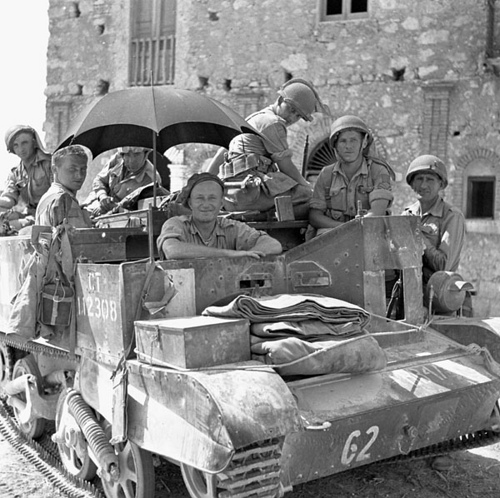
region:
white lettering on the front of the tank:
[331, 423, 381, 459]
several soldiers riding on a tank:
[4, 83, 473, 305]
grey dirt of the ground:
[409, 470, 471, 495]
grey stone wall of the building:
[350, 7, 425, 114]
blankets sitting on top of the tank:
[203, 282, 393, 386]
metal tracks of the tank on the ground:
[18, 431, 79, 496]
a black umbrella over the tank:
[58, 79, 258, 177]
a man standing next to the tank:
[401, 151, 478, 308]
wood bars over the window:
[124, 36, 179, 88]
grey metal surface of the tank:
[221, 374, 283, 425]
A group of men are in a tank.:
[0, 0, 496, 495]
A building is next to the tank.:
[45, 2, 498, 262]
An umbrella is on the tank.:
[51, 60, 256, 248]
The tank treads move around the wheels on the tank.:
[0, 327, 166, 494]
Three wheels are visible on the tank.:
[1, 356, 149, 496]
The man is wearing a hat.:
[175, 168, 225, 219]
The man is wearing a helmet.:
[405, 150, 451, 201]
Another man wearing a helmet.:
[271, 76, 316, 123]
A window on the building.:
[463, 170, 495, 220]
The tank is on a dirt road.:
[0, 292, 499, 497]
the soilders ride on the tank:
[1, 74, 493, 481]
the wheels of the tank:
[1, 352, 147, 495]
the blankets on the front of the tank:
[214, 288, 384, 372]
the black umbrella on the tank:
[77, 74, 269, 157]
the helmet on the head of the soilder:
[324, 111, 374, 155]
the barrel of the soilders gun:
[297, 132, 312, 178]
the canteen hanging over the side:
[42, 273, 77, 341]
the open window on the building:
[461, 173, 498, 218]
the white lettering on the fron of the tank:
[334, 422, 379, 469]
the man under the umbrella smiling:
[161, 166, 286, 259]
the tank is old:
[121, 310, 306, 492]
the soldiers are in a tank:
[5, 66, 470, 223]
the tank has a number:
[311, 418, 398, 475]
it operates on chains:
[178, 419, 290, 495]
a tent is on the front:
[217, 273, 386, 384]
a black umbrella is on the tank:
[73, 73, 263, 286]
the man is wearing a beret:
[150, 160, 251, 229]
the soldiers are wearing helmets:
[262, 72, 434, 204]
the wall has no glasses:
[311, 0, 379, 18]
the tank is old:
[1, 158, 415, 476]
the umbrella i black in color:
[81, 59, 281, 161]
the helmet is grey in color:
[279, 73, 331, 127]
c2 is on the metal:
[343, 426, 384, 469]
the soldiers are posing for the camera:
[21, 85, 499, 295]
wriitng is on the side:
[84, 271, 127, 324]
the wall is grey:
[351, 22, 410, 122]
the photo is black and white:
[1, 8, 497, 489]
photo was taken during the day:
[5, 6, 491, 496]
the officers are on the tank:
[16, 48, 461, 465]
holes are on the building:
[60, 4, 108, 39]